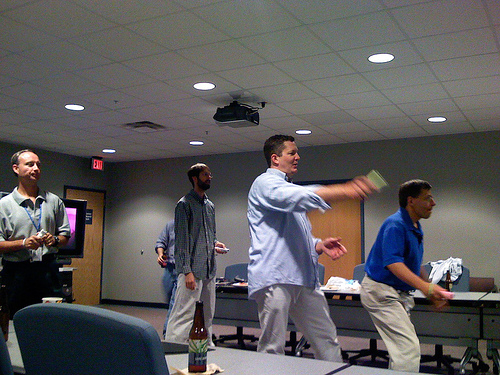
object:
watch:
[54, 235, 61, 242]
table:
[2, 318, 411, 372]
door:
[60, 186, 106, 304]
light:
[366, 52, 396, 65]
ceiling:
[3, 0, 498, 160]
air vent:
[121, 120, 167, 131]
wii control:
[213, 246, 230, 252]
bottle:
[188, 300, 208, 372]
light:
[64, 103, 85, 111]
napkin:
[169, 362, 224, 374]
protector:
[212, 98, 265, 128]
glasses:
[189, 172, 213, 178]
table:
[204, 281, 499, 351]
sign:
[93, 158, 103, 170]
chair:
[12, 302, 170, 375]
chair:
[222, 262, 248, 281]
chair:
[316, 263, 325, 286]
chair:
[353, 264, 365, 285]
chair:
[419, 263, 472, 292]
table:
[448, 289, 497, 372]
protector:
[140, 249, 143, 254]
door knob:
[59, 254, 65, 258]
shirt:
[246, 168, 330, 301]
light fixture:
[367, 53, 395, 65]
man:
[358, 179, 453, 372]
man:
[246, 134, 379, 363]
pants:
[254, 282, 344, 362]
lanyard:
[22, 202, 42, 231]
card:
[28, 243, 49, 262]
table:
[164, 341, 413, 374]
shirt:
[363, 208, 425, 292]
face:
[195, 167, 213, 188]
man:
[164, 163, 230, 349]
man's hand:
[215, 241, 229, 255]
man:
[0, 150, 72, 344]